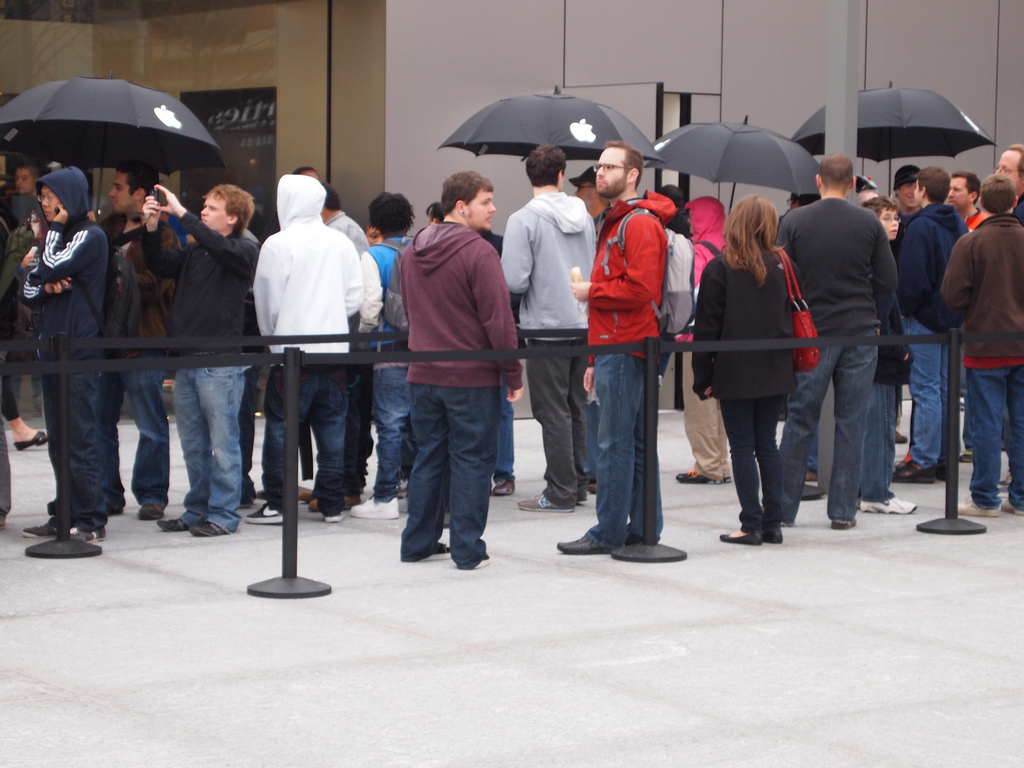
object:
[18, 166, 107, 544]
people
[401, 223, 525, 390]
hoodie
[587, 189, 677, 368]
coat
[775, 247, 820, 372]
purse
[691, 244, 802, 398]
coat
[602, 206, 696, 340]
backpack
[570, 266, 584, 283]
food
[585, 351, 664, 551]
jeans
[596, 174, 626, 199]
beard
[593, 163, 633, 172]
glasses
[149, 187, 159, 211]
camera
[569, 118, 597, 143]
logo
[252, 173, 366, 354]
jacket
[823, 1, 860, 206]
pole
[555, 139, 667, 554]
man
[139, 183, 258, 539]
man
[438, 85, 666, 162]
umbrella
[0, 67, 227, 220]
umbrella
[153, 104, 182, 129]
logo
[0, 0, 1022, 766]
picture